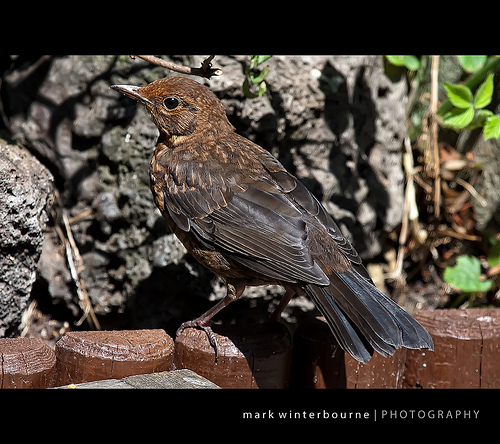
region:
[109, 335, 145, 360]
edge of a pole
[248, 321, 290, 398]
part of a shade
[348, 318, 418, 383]
edge of a tail wing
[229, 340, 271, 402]
edge of a shade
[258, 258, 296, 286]
edge of a feather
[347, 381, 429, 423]
part of a graphic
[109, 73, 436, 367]
A black and brown bird.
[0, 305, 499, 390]
Five brown wood posts.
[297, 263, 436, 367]
A birds tail feathers.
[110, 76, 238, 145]
A birds head and beak.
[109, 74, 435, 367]
A bird on wood posts.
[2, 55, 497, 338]
Rocks in the background.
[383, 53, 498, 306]
Green leaves in background.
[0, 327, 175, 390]
Parts of wood posts.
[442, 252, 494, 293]
One blurry green leaf.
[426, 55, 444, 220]
A brown blurry branch.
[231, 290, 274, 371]
part of a shade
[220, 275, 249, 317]
part of a knee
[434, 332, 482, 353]
edge of a pole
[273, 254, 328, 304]
part of a feather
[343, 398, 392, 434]
part of a graphic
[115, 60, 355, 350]
this is a bird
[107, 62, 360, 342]
the bird is brown in color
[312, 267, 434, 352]
this is the tail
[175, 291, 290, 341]
these are the two legs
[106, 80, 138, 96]
the beak is short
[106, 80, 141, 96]
the beak is sharp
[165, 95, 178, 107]
the eye is open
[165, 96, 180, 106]
the eye is black in color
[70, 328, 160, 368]
this is a wooden fence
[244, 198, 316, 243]
the feathers are folded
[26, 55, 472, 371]
bird perched on wooden pole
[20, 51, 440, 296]
rough grey stone wall behind bird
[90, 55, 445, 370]
bird angled sideways with feet tightly gripping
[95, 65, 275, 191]
short grey arrow of a beak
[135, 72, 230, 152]
short tan and brown feathers surrounding head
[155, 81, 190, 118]
round and black eye open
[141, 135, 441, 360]
three tiers of gray and brown feathers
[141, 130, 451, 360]
feathers lengthening on each tier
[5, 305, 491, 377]
row of poles painted brown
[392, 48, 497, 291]
young green leaves to one side of wall